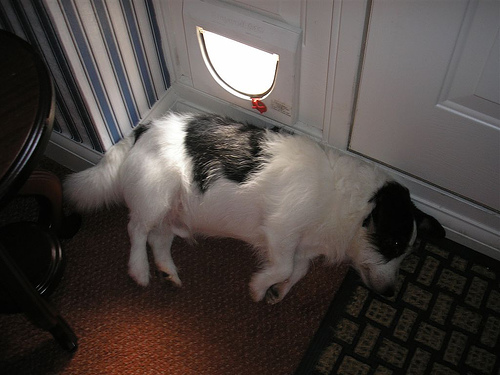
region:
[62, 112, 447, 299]
A dog sleeping on the floor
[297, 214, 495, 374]
A patterned door mat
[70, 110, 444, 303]
A white dog with black patches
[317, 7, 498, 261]
A portion of a white door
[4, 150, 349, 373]
Dark brown carpet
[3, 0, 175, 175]
Column with blue strip pattern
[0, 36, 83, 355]
A brown swivel chair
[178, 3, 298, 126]
A locked pet door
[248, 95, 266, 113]
A small red lock on a pet door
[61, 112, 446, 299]
A small dog lying on the floor next to a entrance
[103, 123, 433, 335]
this is a dog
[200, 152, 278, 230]
the dog is white and black in color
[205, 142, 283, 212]
the dog is hairy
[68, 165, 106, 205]
this is the tail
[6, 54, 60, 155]
this is a table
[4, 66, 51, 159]
the table is wooden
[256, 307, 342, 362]
this is the floor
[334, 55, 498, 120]
this is a cupboard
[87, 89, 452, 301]
the dog is resting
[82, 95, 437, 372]
the dog is lying down on the floor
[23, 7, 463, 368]
The dog is in somebody's house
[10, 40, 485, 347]
The dog is waiting for its master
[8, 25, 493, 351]
The dog is laying by the door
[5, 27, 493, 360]
The dog is guarding the house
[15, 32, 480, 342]
The dog is waiting to be fed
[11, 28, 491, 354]
The dog is awake in daytime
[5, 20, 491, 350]
The dog is waiting to go outside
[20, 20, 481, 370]
A dog is waiting to be let out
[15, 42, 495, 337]
A dog is sleeping on the floor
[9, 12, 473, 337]
A dog is looking for attention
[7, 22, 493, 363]
The dog is looking lonely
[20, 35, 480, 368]
A dog is waiting by the door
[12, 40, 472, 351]
A dog is laying on the floor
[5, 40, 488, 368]
The dog is wanting to be fed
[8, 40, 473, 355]
The dog is enjoying its day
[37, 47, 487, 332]
The dog is getting some rest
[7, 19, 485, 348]
The dog belongs to the home owner